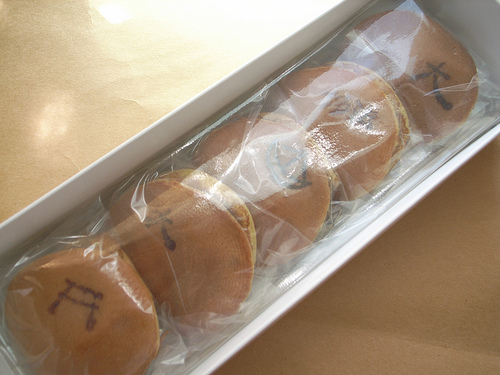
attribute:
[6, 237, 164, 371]
cake — circular in shape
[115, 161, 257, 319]
cake — circular in shape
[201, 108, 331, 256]
cake — circular in shape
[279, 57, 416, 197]
cake — circular in shape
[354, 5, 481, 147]
cake — circular in shape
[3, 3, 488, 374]
pancake — folded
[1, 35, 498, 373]
scene — indoors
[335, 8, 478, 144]
pancake — folded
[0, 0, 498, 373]
bag — transparent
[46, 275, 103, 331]
lettering — black, asian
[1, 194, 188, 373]
plastic — clear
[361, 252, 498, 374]
surface — brown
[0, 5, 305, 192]
paper — brown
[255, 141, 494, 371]
paper — brown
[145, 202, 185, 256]
letter — chinese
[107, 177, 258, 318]
pancake — folded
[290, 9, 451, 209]
plastic wrapping — clear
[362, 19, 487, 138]
fortune cookie — individually wrapped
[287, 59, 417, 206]
fortune cookie — individually wrapped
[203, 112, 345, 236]
fortune cookie — individually wrapped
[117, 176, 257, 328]
fortune cookie — individually wrapped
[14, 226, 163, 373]
fortune cookie — individually wrapped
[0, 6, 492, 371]
box — white, open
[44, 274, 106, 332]
letter — chocolate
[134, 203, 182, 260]
letter — chocolate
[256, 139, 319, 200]
letter — chocolate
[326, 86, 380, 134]
letter — chocolate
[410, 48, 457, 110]
letter — chocolate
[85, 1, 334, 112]
reflection — light